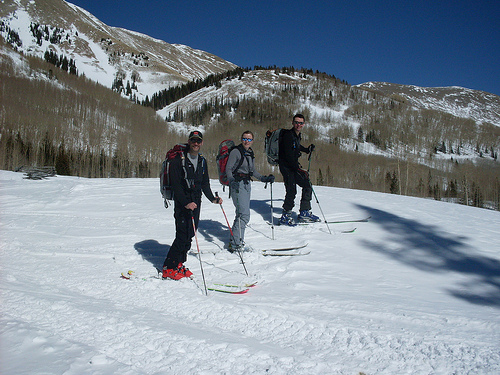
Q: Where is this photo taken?
A: On the ski slopes.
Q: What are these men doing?
A: Skiing.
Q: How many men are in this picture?
A: Three.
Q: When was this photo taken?
A: Daytime.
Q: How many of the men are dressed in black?
A: Two.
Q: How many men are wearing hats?
A: One.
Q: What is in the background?
A: Wooded hillside.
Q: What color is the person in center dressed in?
A: Gray.